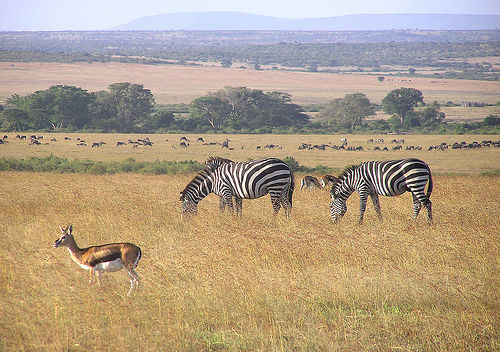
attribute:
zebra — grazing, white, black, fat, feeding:
[173, 154, 298, 225]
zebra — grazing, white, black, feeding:
[327, 155, 435, 226]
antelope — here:
[49, 229, 145, 299]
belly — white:
[93, 256, 126, 277]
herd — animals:
[0, 124, 499, 154]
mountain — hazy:
[121, 10, 499, 31]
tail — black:
[424, 165, 434, 207]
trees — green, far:
[2, 82, 500, 132]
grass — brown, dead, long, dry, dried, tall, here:
[1, 169, 500, 345]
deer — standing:
[54, 223, 151, 296]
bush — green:
[4, 156, 354, 174]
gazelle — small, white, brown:
[53, 217, 148, 300]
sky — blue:
[4, 0, 500, 35]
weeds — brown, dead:
[4, 172, 499, 348]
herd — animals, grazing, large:
[5, 122, 498, 149]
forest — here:
[6, 28, 499, 78]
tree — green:
[182, 89, 303, 138]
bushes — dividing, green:
[1, 76, 496, 137]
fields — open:
[4, 62, 499, 348]